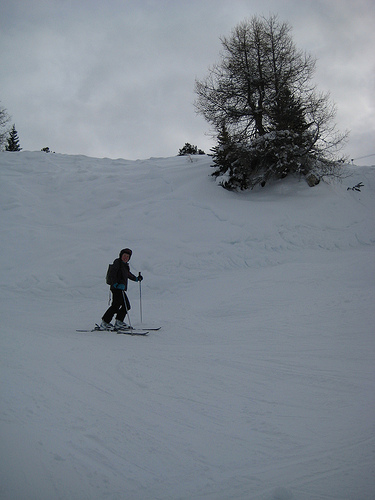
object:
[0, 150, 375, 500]
snow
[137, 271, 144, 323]
pole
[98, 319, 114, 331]
boots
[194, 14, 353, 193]
tree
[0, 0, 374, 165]
sky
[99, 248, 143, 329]
boy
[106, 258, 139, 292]
jacket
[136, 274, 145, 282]
glove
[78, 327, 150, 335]
ski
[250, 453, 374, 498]
tracks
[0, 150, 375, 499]
hill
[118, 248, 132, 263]
head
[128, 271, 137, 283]
arm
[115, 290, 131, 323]
leg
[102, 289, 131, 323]
pants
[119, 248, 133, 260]
hat